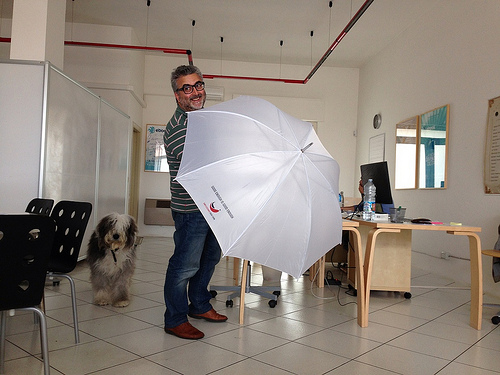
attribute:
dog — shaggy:
[86, 210, 141, 309]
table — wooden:
[343, 215, 483, 329]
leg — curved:
[362, 227, 401, 327]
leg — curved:
[446, 231, 483, 330]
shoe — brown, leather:
[157, 313, 204, 341]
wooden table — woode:
[233, 216, 365, 326]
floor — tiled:
[266, 318, 386, 373]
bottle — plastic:
[356, 171, 384, 219]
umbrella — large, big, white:
[173, 87, 358, 286]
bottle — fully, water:
[359, 176, 377, 219]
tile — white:
[249, 340, 350, 374]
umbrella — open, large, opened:
[177, 88, 349, 275]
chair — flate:
[21, 193, 50, 217]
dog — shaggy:
[86, 215, 147, 313]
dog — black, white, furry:
[88, 212, 155, 312]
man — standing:
[160, 62, 231, 340]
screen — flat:
[358, 156, 397, 206]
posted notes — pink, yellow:
[431, 216, 464, 228]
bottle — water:
[354, 178, 381, 222]